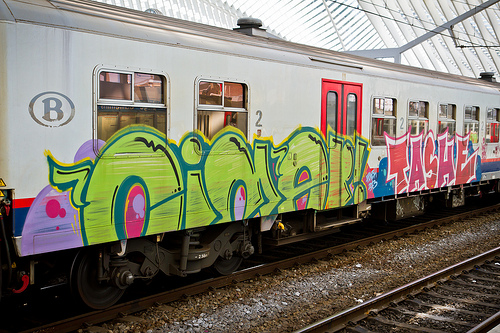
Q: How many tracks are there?
A: Two.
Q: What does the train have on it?
A: Graffiti.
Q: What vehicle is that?
A: Train.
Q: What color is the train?
A: White.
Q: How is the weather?
A: Sunny.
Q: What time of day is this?
A: Afternoon.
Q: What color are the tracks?
A: Brown.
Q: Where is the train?
A: Along train tracks.